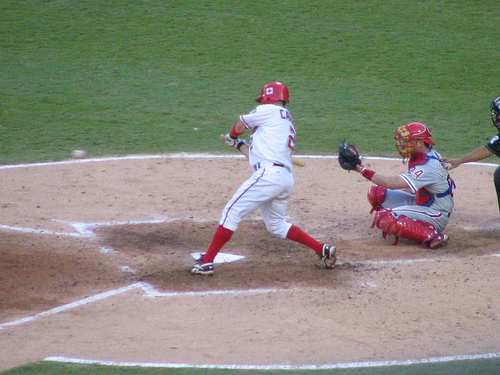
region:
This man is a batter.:
[180, 60, 325, 272]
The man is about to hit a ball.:
[170, 48, 344, 293]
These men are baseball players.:
[193, 58, 465, 305]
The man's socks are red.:
[193, 222, 233, 262]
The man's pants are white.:
[216, 173, 310, 228]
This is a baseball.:
[44, 140, 110, 186]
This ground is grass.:
[42, 7, 222, 99]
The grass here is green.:
[30, 8, 221, 121]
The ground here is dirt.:
[30, 225, 183, 348]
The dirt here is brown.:
[3, 214, 143, 316]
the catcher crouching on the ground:
[338, 123, 455, 249]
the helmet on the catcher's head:
[396, 123, 434, 144]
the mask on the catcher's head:
[395, 126, 413, 158]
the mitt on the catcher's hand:
[336, 138, 361, 171]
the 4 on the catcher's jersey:
[413, 168, 423, 179]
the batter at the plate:
[189, 80, 336, 273]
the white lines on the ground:
[1, 154, 499, 369]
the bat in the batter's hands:
[220, 132, 305, 167]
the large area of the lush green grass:
[1, 0, 498, 165]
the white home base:
[191, 250, 245, 265]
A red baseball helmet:
[250, 76, 295, 106]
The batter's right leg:
[191, 219, 232, 280]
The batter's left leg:
[282, 217, 350, 282]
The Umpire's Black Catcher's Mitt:
[330, 131, 363, 176]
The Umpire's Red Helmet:
[393, 121, 438, 159]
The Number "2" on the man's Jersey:
[280, 122, 300, 157]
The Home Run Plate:
[194, 244, 244, 269]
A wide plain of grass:
[0, 8, 144, 142]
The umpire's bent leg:
[379, 202, 452, 253]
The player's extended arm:
[441, 146, 491, 189]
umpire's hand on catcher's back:
[436, 143, 494, 211]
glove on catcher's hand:
[338, 137, 365, 175]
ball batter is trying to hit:
[66, 133, 89, 164]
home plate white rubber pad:
[188, 243, 245, 273]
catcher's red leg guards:
[364, 183, 444, 246]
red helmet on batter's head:
[254, 77, 293, 105]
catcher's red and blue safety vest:
[401, 148, 459, 210]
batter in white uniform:
[189, 75, 342, 285]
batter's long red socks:
[197, 223, 327, 265]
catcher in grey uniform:
[335, 120, 457, 257]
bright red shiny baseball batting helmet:
[254, 81, 289, 105]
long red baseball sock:
[285, 222, 323, 257]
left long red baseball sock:
[200, 221, 232, 261]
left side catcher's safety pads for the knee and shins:
[369, 207, 446, 249]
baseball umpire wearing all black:
[438, 95, 498, 213]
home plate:
[189, 250, 246, 264]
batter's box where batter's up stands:
[0, 215, 346, 328]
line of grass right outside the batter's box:
[0, 359, 498, 373]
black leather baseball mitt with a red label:
[337, 137, 361, 171]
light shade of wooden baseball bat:
[217, 133, 305, 167]